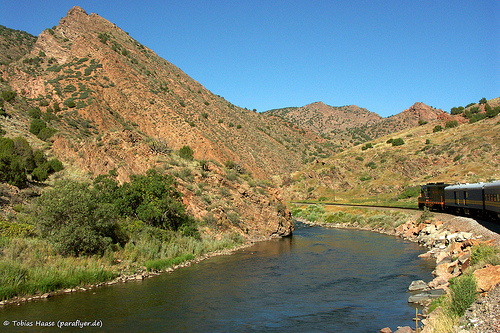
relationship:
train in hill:
[415, 177, 498, 231] [385, 102, 464, 177]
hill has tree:
[16, 2, 280, 200] [73, 55, 88, 65]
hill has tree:
[16, 2, 280, 200] [63, 82, 78, 94]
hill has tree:
[16, 2, 280, 200] [75, 99, 85, 111]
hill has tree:
[16, 2, 280, 200] [46, 63, 62, 72]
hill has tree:
[16, 2, 280, 200] [37, 125, 54, 141]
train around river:
[415, 177, 498, 231] [0, 207, 441, 331]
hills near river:
[1, 9, 497, 225] [0, 224, 436, 327]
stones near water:
[385, 222, 474, 331] [0, 217, 432, 330]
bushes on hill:
[453, 105, 470, 122] [385, 102, 464, 177]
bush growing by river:
[33, 167, 201, 254] [0, 224, 436, 327]